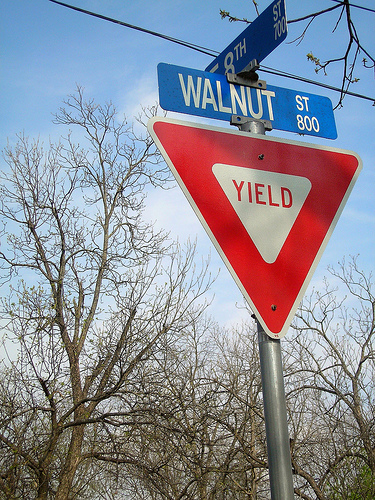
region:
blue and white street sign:
[157, 61, 337, 139]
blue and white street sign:
[205, 0, 288, 72]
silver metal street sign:
[256, 316, 295, 499]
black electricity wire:
[47, 1, 374, 103]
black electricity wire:
[335, 0, 374, 11]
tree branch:
[217, 0, 373, 111]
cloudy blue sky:
[0, 0, 373, 387]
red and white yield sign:
[147, 115, 362, 341]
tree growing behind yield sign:
[0, 82, 221, 498]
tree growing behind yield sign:
[284, 252, 372, 498]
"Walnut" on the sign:
[149, 60, 354, 141]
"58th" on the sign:
[171, 7, 311, 77]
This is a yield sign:
[140, 114, 351, 343]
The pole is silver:
[235, 317, 318, 499]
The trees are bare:
[3, 95, 337, 499]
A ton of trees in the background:
[1, 85, 362, 499]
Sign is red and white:
[138, 115, 360, 343]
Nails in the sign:
[249, 144, 293, 315]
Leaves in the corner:
[316, 431, 374, 494]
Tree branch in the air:
[213, 7, 362, 110]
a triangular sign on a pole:
[131, 110, 373, 350]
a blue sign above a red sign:
[146, 53, 343, 141]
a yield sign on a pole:
[145, 112, 367, 375]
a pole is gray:
[245, 316, 307, 498]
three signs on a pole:
[141, 2, 363, 383]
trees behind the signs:
[6, 93, 372, 498]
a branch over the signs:
[203, 0, 373, 122]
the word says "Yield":
[136, 104, 369, 342]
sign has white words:
[151, 56, 347, 141]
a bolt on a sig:
[263, 296, 284, 319]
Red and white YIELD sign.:
[142, 112, 370, 495]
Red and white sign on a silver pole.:
[143, 115, 363, 499]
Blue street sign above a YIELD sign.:
[152, 58, 346, 141]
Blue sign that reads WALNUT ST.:
[152, 59, 344, 139]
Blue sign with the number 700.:
[207, 2, 288, 72]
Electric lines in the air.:
[55, 2, 371, 110]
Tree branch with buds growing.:
[213, 0, 373, 103]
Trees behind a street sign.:
[0, 72, 207, 496]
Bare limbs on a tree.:
[0, 131, 198, 499]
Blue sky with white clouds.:
[4, 2, 365, 309]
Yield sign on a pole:
[143, 107, 335, 347]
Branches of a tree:
[48, 105, 145, 292]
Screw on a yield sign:
[263, 293, 281, 316]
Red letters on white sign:
[220, 175, 302, 210]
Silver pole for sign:
[253, 335, 300, 441]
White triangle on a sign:
[208, 156, 319, 266]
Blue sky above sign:
[148, 176, 208, 248]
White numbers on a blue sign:
[293, 104, 323, 134]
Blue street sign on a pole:
[161, 62, 334, 132]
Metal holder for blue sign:
[228, 113, 273, 129]